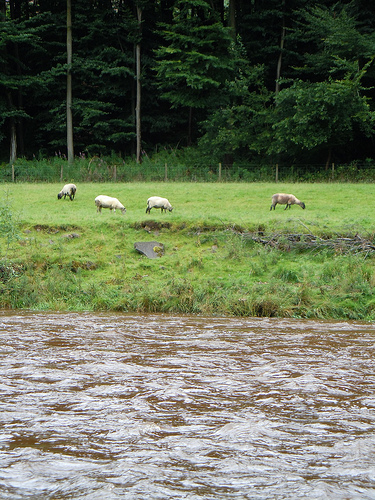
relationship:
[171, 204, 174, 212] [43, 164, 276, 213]
head of sheep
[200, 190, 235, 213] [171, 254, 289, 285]
grass in field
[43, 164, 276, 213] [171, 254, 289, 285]
sheep in field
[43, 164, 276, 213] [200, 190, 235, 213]
sheep in grass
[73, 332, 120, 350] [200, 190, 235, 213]
river near grass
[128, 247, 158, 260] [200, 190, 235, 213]
rock in grass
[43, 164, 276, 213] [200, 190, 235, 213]
sheep eating grass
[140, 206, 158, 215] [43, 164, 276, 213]
leg of sheep